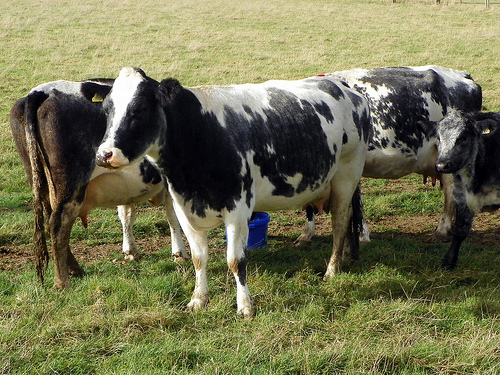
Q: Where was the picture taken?
A: It was taken at the field.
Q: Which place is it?
A: It is a field.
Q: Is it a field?
A: Yes, it is a field.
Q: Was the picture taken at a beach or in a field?
A: It was taken at a field.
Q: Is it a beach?
A: No, it is a field.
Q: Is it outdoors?
A: Yes, it is outdoors.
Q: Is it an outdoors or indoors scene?
A: It is outdoors.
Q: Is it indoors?
A: No, it is outdoors.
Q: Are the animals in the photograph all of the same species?
A: Yes, all the animals are cows.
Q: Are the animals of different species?
A: No, all the animals are cows.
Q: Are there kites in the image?
A: No, there are no kites.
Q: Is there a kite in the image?
A: No, there are no kites.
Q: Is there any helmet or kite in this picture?
A: No, there are no kites or helmets.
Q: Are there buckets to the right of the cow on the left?
A: Yes, there is a bucket to the right of the cow.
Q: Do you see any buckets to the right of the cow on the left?
A: Yes, there is a bucket to the right of the cow.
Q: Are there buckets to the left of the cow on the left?
A: No, the bucket is to the right of the cow.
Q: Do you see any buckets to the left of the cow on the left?
A: No, the bucket is to the right of the cow.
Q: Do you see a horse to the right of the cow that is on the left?
A: No, there is a bucket to the right of the cow.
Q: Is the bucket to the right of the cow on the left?
A: Yes, the bucket is to the right of the cow.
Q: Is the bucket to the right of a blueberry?
A: No, the bucket is to the right of the cow.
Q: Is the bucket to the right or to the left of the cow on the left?
A: The bucket is to the right of the cow.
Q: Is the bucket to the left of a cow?
A: Yes, the bucket is to the left of a cow.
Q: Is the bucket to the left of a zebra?
A: No, the bucket is to the left of a cow.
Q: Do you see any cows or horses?
A: Yes, there is a cow.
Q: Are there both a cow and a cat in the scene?
A: No, there is a cow but no cats.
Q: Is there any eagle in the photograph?
A: No, there are no eagles.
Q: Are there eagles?
A: No, there are no eagles.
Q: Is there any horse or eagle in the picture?
A: No, there are no eagles or horses.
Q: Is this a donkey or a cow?
A: This is a cow.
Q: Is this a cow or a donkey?
A: This is a cow.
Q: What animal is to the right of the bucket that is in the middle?
A: The animal is a cow.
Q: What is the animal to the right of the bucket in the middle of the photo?
A: The animal is a cow.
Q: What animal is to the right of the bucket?
A: The animal is a cow.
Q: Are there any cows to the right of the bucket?
A: Yes, there is a cow to the right of the bucket.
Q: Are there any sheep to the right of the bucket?
A: No, there is a cow to the right of the bucket.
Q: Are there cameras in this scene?
A: Yes, there is a camera.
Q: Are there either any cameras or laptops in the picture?
A: Yes, there is a camera.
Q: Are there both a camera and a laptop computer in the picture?
A: No, there is a camera but no laptops.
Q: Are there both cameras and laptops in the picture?
A: No, there is a camera but no laptops.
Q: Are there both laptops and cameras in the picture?
A: No, there is a camera but no laptops.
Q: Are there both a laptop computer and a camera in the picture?
A: No, there is a camera but no laptops.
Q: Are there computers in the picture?
A: No, there are no computers.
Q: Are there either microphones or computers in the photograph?
A: No, there are no computers or microphones.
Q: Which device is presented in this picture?
A: The device is a camera.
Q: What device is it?
A: The device is a camera.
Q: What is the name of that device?
A: This is a camera.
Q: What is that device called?
A: This is a camera.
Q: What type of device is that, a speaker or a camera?
A: This is a camera.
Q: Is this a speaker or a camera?
A: This is a camera.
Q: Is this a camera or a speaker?
A: This is a camera.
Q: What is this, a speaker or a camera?
A: This is a camera.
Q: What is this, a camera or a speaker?
A: This is a camera.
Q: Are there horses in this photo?
A: No, there are no horses.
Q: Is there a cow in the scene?
A: Yes, there is a cow.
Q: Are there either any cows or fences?
A: Yes, there is a cow.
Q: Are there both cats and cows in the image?
A: No, there is a cow but no cats.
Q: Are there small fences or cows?
A: Yes, there is a small cow.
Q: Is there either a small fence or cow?
A: Yes, there is a small cow.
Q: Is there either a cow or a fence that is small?
A: Yes, the cow is small.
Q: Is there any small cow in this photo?
A: Yes, there is a small cow.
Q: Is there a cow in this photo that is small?
A: Yes, there is a cow that is small.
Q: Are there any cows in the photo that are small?
A: Yes, there is a cow that is small.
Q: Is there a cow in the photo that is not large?
A: Yes, there is a small cow.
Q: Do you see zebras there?
A: No, there are no zebras.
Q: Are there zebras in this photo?
A: No, there are no zebras.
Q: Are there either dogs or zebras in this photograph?
A: No, there are no zebras or dogs.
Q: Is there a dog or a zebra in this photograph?
A: No, there are no zebras or dogs.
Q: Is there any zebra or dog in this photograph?
A: No, there are no zebras or dogs.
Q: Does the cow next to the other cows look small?
A: Yes, the cow is small.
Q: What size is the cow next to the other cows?
A: The cow is small.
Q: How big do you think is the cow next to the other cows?
A: The cow is small.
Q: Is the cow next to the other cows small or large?
A: The cow is small.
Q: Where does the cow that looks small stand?
A: The cow stands in the field.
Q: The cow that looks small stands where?
A: The cow stands in the field.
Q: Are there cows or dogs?
A: Yes, there is a cow.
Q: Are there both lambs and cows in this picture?
A: No, there is a cow but no lambs.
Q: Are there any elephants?
A: No, there are no elephants.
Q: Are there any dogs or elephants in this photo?
A: No, there are no elephants or dogs.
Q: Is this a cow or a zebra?
A: This is a cow.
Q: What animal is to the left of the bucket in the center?
A: The animal is a cow.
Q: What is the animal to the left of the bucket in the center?
A: The animal is a cow.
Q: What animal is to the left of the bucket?
A: The animal is a cow.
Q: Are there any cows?
A: Yes, there are cows.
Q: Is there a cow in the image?
A: Yes, there are cows.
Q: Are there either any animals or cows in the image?
A: Yes, there are cows.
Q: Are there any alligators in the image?
A: No, there are no alligators.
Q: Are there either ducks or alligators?
A: No, there are no alligators or ducks.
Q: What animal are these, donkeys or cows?
A: These are cows.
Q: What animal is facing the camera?
A: The cows are facing the camera.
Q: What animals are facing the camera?
A: The animals are cows.